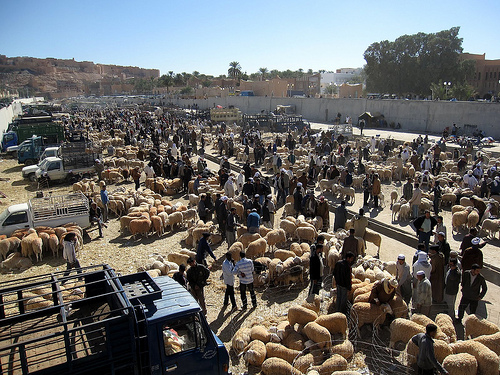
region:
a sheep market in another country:
[10, 93, 489, 373]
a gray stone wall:
[209, 68, 499, 146]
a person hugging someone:
[198, 247, 269, 307]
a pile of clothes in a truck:
[148, 313, 195, 373]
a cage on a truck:
[5, 262, 167, 373]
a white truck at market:
[0, 175, 95, 252]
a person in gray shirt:
[398, 321, 453, 373]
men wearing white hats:
[395, 256, 429, 284]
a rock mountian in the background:
[0, 51, 189, 111]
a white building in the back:
[308, 63, 370, 82]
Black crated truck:
[1, 260, 218, 373]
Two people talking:
[222, 243, 259, 314]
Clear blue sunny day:
[162, 3, 245, 55]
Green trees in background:
[368, 22, 488, 107]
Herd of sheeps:
[226, 299, 359, 374]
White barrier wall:
[310, 95, 356, 120]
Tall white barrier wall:
[314, 90, 469, 132]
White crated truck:
[1, 188, 108, 245]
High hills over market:
[21, 57, 132, 96]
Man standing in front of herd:
[402, 323, 447, 373]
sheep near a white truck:
[0, 192, 89, 260]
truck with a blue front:
[2, 261, 234, 373]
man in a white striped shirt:
[234, 246, 259, 315]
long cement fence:
[146, 87, 498, 135]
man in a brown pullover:
[458, 259, 488, 322]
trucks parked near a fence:
[0, 106, 99, 188]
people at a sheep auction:
[1, 80, 495, 370]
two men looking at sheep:
[214, 237, 290, 314]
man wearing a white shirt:
[56, 230, 91, 286]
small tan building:
[336, 77, 366, 97]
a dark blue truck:
[3, 268, 219, 368]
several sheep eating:
[241, 307, 356, 371]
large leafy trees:
[358, 39, 482, 104]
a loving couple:
[220, 252, 257, 308]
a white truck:
[7, 197, 89, 231]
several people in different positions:
[408, 217, 488, 313]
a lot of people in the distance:
[63, 101, 205, 127]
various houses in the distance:
[163, 74, 357, 101]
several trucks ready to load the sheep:
[13, 132, 96, 182]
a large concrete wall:
[268, 94, 498, 130]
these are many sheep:
[233, 253, 496, 369]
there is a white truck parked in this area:
[2, 189, 101, 240]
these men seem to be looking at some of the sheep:
[219, 247, 262, 318]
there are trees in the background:
[366, 30, 493, 105]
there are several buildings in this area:
[26, 53, 251, 101]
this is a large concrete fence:
[169, 90, 498, 135]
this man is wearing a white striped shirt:
[236, 260, 252, 290]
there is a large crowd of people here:
[136, 126, 494, 341]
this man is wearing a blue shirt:
[96, 191, 115, 206]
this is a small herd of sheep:
[228, 303, 379, 373]